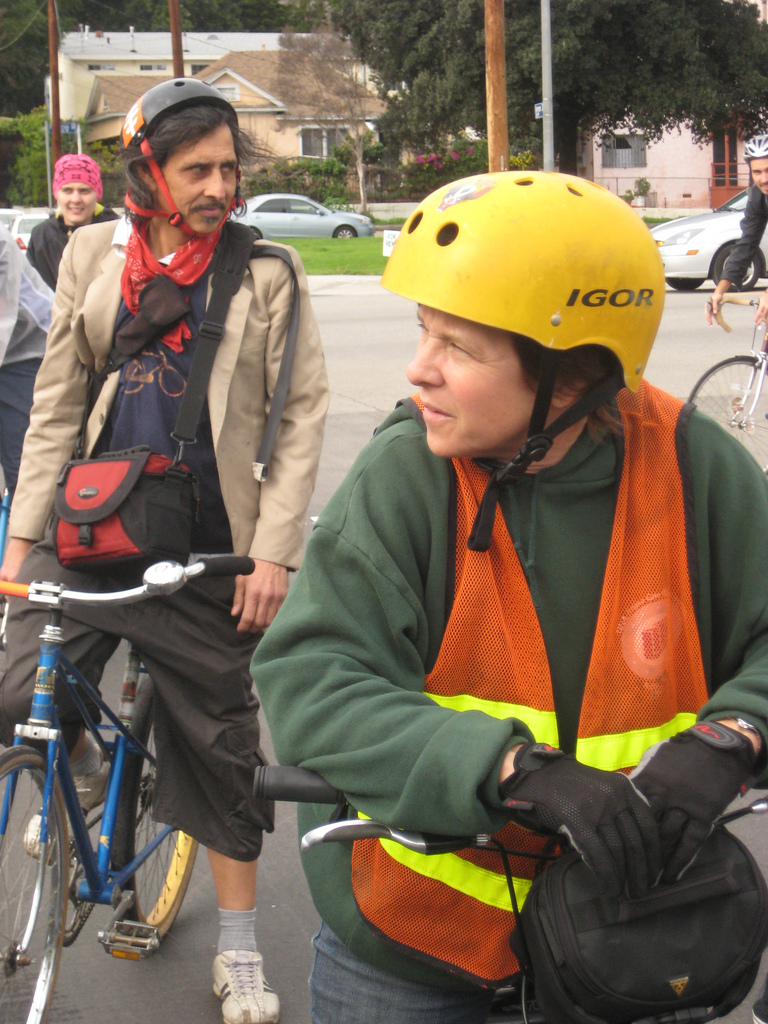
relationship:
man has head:
[250, 159, 768, 1023] [383, 172, 666, 462]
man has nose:
[250, 159, 768, 1023] [409, 339, 445, 386]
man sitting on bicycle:
[3, 79, 333, 1017] [3, 548, 255, 1021]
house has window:
[577, 113, 764, 219] [601, 137, 645, 171]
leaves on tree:
[327, 6, 765, 145] [320, 2, 766, 177]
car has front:
[649, 187, 764, 286] [649, 215, 764, 277]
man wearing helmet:
[251, 143, 734, 1001] [374, 166, 663, 388]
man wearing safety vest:
[251, 143, 734, 1001] [346, 378, 710, 983]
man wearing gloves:
[250, 159, 768, 1023] [476, 716, 737, 905]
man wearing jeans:
[251, 143, 734, 1001] [292, 910, 491, 1017]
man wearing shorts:
[3, 79, 333, 1017] [10, 525, 276, 862]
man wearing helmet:
[3, 79, 333, 1017] [117, 75, 248, 253]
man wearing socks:
[0, 79, 334, 1018] [217, 906, 258, 953]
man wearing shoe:
[3, 79, 333, 1017] [208, 941, 282, 1021]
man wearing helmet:
[250, 159, 768, 1023] [374, 166, 663, 388]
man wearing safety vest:
[250, 159, 768, 1023] [346, 378, 710, 983]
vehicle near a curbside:
[229, 192, 374, 238] [264, 230, 406, 252]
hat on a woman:
[49, 152, 104, 199] [22, 153, 121, 288]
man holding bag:
[250, 159, 768, 1023] [505, 811, 763, 1021]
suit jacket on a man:
[1, 215, 331, 569] [3, 79, 333, 1017]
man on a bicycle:
[3, 79, 333, 1017] [0, 554, 258, 1021]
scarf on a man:
[117, 206, 235, 348] [3, 79, 333, 1017]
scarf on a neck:
[117, 206, 235, 348] [141, 220, 188, 252]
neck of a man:
[141, 220, 188, 252] [3, 79, 333, 1017]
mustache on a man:
[191, 201, 227, 213] [3, 79, 333, 1017]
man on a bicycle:
[0, 79, 334, 1018] [3, 548, 255, 1021]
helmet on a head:
[374, 166, 663, 388] [412, 235, 636, 464]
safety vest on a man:
[350, 378, 710, 991] [250, 159, 768, 1023]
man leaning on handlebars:
[250, 159, 768, 1023] [301, 784, 763, 856]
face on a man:
[167, 134, 234, 235] [0, 79, 334, 1018]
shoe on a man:
[208, 940, 282, 1024] [3, 79, 333, 1017]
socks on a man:
[65, 740, 256, 952] [3, 79, 333, 1017]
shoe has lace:
[208, 941, 282, 1021] [230, 945, 263, 1020]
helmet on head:
[375, 167, 672, 393] [389, 258, 651, 467]